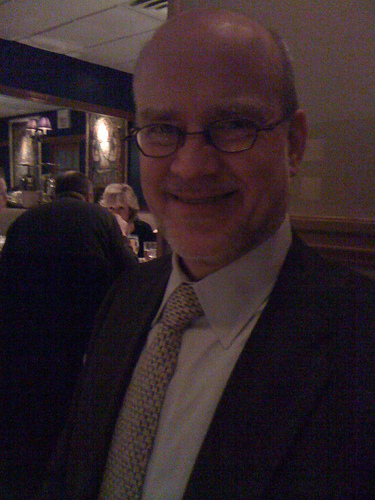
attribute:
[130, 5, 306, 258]
head — whole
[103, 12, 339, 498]
man — balding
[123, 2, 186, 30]
vent — white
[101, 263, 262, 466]
shirt — white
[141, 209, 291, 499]
shirt — lavender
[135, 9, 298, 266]
head — bald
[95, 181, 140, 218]
hair — light colored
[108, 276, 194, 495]
tie — long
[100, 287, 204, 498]
tie — multi colored